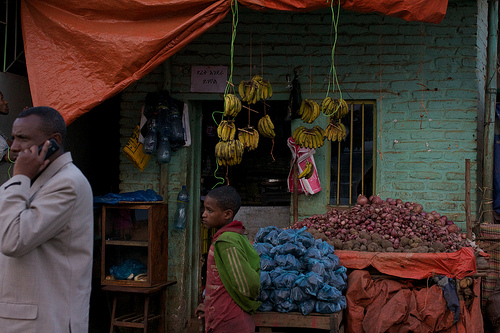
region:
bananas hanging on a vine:
[202, 56, 299, 191]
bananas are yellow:
[199, 55, 282, 177]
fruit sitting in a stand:
[282, 182, 464, 298]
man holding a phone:
[6, 104, 91, 205]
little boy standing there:
[177, 162, 324, 324]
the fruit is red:
[314, 177, 467, 285]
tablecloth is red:
[335, 243, 498, 285]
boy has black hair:
[192, 177, 262, 222]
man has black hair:
[4, 97, 77, 152]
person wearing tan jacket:
[5, 105, 100, 330]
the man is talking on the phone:
[4, 113, 81, 180]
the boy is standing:
[192, 181, 252, 261]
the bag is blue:
[282, 240, 312, 288]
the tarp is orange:
[53, 36, 91, 68]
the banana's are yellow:
[218, 119, 243, 142]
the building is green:
[409, 100, 444, 139]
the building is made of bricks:
[411, 116, 448, 163]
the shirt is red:
[207, 278, 224, 307]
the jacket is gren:
[226, 244, 250, 274]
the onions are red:
[350, 186, 392, 208]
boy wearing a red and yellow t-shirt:
[182, 171, 273, 323]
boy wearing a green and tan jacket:
[200, 182, 257, 322]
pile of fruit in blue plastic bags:
[244, 210, 352, 327]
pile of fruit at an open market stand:
[319, 182, 461, 261]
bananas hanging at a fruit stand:
[213, 61, 360, 182]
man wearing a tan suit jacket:
[1, 103, 102, 318]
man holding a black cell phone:
[2, 97, 88, 290]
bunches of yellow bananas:
[212, 118, 270, 167]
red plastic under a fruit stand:
[355, 242, 482, 324]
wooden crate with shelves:
[96, 179, 184, 306]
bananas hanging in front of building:
[215, 74, 346, 164]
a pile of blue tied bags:
[248, 225, 346, 317]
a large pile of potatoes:
[289, 196, 464, 249]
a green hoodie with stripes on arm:
[211, 230, 266, 313]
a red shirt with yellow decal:
[204, 221, 250, 331]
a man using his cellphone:
[3, 107, 89, 332]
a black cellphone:
[32, 138, 58, 156]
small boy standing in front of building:
[200, 185, 263, 332]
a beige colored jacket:
[0, 154, 93, 329]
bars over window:
[329, 98, 376, 210]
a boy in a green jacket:
[193, 179, 265, 330]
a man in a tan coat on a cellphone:
[4, 100, 92, 331]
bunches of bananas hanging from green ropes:
[213, 1, 352, 164]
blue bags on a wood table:
[248, 220, 349, 317]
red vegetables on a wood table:
[281, 195, 471, 258]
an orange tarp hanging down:
[17, 2, 450, 124]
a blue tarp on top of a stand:
[96, 188, 167, 206]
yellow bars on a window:
[326, 93, 378, 212]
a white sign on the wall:
[185, 60, 232, 94]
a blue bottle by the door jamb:
[171, 183, 193, 233]